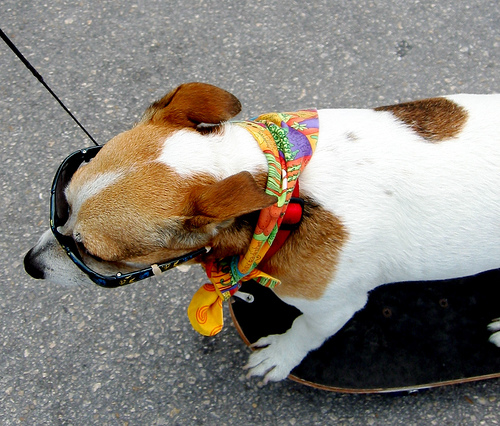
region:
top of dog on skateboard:
[40, 66, 489, 400]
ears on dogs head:
[155, 72, 262, 228]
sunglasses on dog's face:
[35, 135, 180, 292]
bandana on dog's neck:
[215, 96, 320, 296]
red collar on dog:
[280, 185, 307, 252]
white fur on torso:
[384, 213, 489, 276]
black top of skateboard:
[358, 275, 480, 377]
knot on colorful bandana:
[202, 262, 253, 298]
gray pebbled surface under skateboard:
[93, 326, 256, 403]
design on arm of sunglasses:
[114, 255, 191, 290]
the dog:
[50, 106, 325, 298]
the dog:
[79, 121, 412, 418]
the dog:
[19, 44, 284, 381]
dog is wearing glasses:
[23, 127, 188, 302]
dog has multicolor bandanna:
[202, 61, 354, 342]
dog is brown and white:
[220, 63, 437, 285]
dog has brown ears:
[127, 39, 233, 144]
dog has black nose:
[7, 247, 52, 282]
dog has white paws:
[245, 321, 274, 395]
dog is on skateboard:
[242, 218, 466, 391]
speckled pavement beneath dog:
[140, 1, 375, 95]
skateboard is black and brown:
[226, 231, 497, 402]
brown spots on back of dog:
[294, 81, 463, 254]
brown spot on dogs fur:
[386, 102, 467, 139]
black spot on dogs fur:
[341, 123, 359, 148]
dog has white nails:
[242, 363, 255, 382]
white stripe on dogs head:
[81, 171, 123, 193]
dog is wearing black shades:
[41, 157, 113, 291]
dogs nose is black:
[18, 247, 48, 284]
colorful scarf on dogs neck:
[251, 112, 313, 177]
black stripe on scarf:
[288, 193, 305, 209]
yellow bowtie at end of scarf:
[183, 287, 230, 346]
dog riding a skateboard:
[45, 119, 497, 391]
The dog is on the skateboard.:
[13, 40, 496, 415]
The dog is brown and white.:
[21, 56, 496, 408]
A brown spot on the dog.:
[380, 82, 471, 149]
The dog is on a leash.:
[0, 30, 110, 156]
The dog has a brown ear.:
[140, 55, 243, 143]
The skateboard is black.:
[198, 281, 498, 412]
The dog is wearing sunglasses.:
[40, 101, 220, 316]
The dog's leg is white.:
[230, 315, 321, 401]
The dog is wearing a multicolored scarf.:
[183, 111, 321, 363]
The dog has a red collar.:
[251, 187, 314, 278]